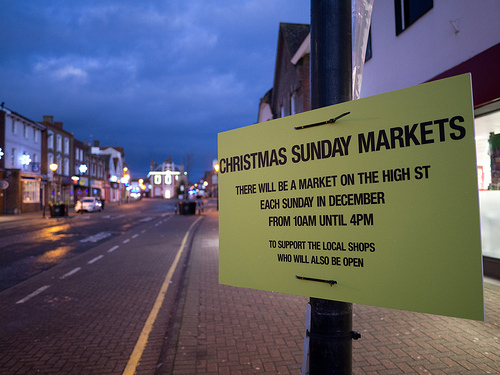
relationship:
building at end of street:
[142, 155, 193, 204] [0, 200, 203, 372]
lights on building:
[18, 154, 32, 165] [1, 100, 131, 209]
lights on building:
[78, 162, 88, 173] [1, 100, 131, 209]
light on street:
[45, 158, 62, 212] [0, 200, 203, 372]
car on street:
[72, 194, 104, 217] [0, 200, 203, 372]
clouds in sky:
[25, 2, 260, 121] [1, 0, 309, 184]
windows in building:
[3, 116, 118, 182] [1, 100, 131, 209]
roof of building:
[277, 20, 313, 57] [267, 18, 311, 121]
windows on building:
[3, 116, 118, 182] [1, 100, 131, 209]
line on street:
[121, 213, 206, 374] [0, 200, 203, 372]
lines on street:
[13, 206, 178, 308] [0, 200, 203, 372]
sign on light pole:
[214, 69, 485, 319] [308, 0, 360, 375]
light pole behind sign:
[308, 0, 360, 375] [214, 69, 485, 319]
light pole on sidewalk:
[308, 0, 360, 375] [170, 199, 499, 374]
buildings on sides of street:
[2, 103, 125, 219] [0, 200, 203, 372]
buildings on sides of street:
[255, 3, 499, 282] [0, 200, 203, 372]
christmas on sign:
[217, 146, 288, 176] [214, 69, 485, 319]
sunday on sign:
[288, 132, 354, 167] [214, 69, 485, 319]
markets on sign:
[357, 115, 468, 159] [214, 69, 485, 319]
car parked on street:
[72, 194, 104, 217] [0, 200, 203, 372]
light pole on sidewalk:
[308, 0, 354, 375] [170, 199, 499, 374]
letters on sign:
[216, 112, 469, 270] [214, 69, 485, 319]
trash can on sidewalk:
[176, 197, 200, 218] [170, 199, 499, 374]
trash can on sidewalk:
[51, 199, 68, 221] [1, 210, 104, 234]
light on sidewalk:
[49, 163, 57, 204] [1, 210, 104, 234]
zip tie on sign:
[292, 107, 352, 132] [214, 69, 485, 319]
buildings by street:
[2, 103, 125, 219] [0, 200, 203, 372]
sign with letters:
[214, 69, 485, 319] [216, 112, 469, 270]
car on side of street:
[72, 194, 104, 217] [0, 200, 203, 372]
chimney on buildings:
[38, 109, 70, 132] [2, 103, 125, 219]